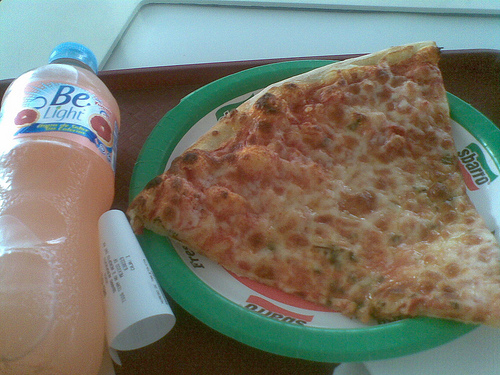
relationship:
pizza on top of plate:
[128, 41, 500, 326] [127, 57, 494, 363]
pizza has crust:
[128, 41, 500, 326] [121, 41, 440, 233]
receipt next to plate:
[98, 207, 177, 366] [127, 57, 494, 363]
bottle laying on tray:
[0, 41, 122, 375] [1, 48, 500, 375]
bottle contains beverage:
[0, 41, 122, 375] [1, 66, 122, 375]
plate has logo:
[127, 57, 494, 363] [241, 295, 314, 329]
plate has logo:
[127, 57, 494, 363] [455, 141, 499, 192]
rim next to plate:
[128, 58, 342, 204] [127, 57, 494, 363]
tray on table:
[1, 48, 500, 375] [0, 0, 500, 80]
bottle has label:
[0, 41, 122, 375] [1, 82, 120, 173]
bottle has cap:
[0, 41, 122, 375] [49, 41, 97, 75]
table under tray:
[0, 0, 500, 80] [1, 48, 500, 375]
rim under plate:
[128, 58, 342, 204] [127, 57, 494, 363]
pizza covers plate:
[128, 41, 500, 326] [127, 57, 494, 363]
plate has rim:
[127, 57, 494, 363] [128, 58, 342, 204]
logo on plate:
[455, 141, 499, 192] [127, 57, 494, 363]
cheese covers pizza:
[155, 56, 500, 325] [128, 41, 500, 326]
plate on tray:
[127, 57, 494, 363] [1, 48, 500, 375]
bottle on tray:
[0, 41, 122, 375] [1, 48, 500, 375]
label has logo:
[1, 82, 120, 173] [44, 84, 92, 126]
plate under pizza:
[127, 57, 494, 363] [128, 41, 500, 326]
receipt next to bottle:
[98, 207, 177, 366] [0, 41, 122, 375]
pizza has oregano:
[128, 41, 500, 326] [389, 232, 401, 248]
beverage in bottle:
[1, 66, 122, 375] [0, 41, 122, 375]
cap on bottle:
[49, 41, 97, 75] [0, 41, 122, 375]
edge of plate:
[203, 322, 398, 360] [127, 57, 494, 363]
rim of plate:
[128, 58, 342, 204] [127, 57, 494, 363]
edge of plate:
[142, 254, 473, 361] [127, 57, 494, 363]